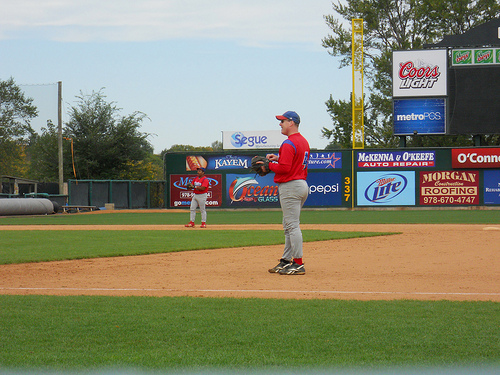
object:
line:
[11, 285, 496, 297]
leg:
[279, 198, 302, 261]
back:
[295, 138, 310, 177]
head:
[279, 111, 301, 137]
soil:
[412, 235, 459, 287]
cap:
[275, 111, 300, 124]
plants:
[28, 85, 162, 180]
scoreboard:
[445, 46, 498, 134]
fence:
[164, 144, 497, 207]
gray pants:
[277, 179, 310, 260]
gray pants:
[190, 193, 208, 222]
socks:
[294, 258, 303, 266]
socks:
[283, 254, 291, 263]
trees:
[27, 86, 158, 183]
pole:
[350, 13, 364, 147]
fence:
[66, 178, 168, 210]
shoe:
[268, 258, 292, 273]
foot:
[269, 257, 291, 273]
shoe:
[279, 261, 307, 275]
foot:
[280, 260, 305, 275]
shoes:
[199, 221, 206, 228]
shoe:
[185, 221, 195, 228]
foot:
[185, 221, 196, 228]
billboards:
[164, 127, 500, 206]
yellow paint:
[342, 177, 352, 202]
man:
[184, 167, 208, 229]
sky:
[1, 0, 498, 157]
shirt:
[191, 175, 209, 196]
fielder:
[264, 111, 308, 277]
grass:
[185, 303, 387, 367]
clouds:
[3, 4, 330, 38]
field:
[0, 204, 497, 375]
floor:
[4, 210, 499, 370]